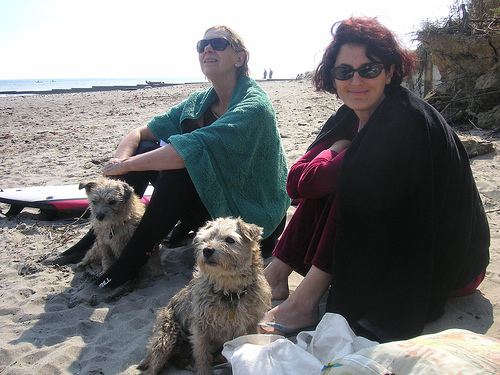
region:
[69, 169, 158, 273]
white and tan dog facing down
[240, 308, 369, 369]
white towel bunched up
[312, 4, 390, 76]
red burgundy short hair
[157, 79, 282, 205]
light green towel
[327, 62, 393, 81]
black cat eye shades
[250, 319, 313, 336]
white flip flops on a woman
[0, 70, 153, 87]
clear blue water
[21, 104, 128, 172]
brown disturbed sand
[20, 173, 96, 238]
red and white surfboard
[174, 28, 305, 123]
woman with blonde hair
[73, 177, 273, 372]
two tan colored dogs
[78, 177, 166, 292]
a dog looking down at the sand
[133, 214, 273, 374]
a dog looking upwards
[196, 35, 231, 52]
a pair of sunglasses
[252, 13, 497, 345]
woman with reddish colored hair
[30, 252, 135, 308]
feet buried in the sand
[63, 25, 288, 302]
a woman wearing a green shawl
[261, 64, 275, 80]
two people walking on the shore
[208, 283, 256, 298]
a dog's black collar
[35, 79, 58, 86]
people in the water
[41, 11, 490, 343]
two women sitting on the beach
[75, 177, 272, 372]
two dogs sitting on the beach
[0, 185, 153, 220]
a white and pink flotation device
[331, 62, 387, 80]
a pair of sunglasses on the woman's face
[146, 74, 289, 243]
a green towel on the woman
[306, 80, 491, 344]
a black towel on the woman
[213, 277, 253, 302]
a black dog collar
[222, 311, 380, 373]
a white bag on the ground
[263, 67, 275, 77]
two people standing in the distance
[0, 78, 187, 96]
ocean next to the beach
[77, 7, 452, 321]
Two dogs are on the beach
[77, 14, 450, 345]
Two women are sitting on the beach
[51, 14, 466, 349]
The photo was taken during the day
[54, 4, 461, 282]
Both women are wearing sunglasses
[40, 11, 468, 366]
Photo was taken during the day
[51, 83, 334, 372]
The dogs are the same breed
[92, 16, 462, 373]
Women are sitting on sand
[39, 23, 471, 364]
Women are sitting on the beach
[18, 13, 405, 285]
The ocean is in the background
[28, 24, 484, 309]
The women are looking in different directions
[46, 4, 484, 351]
Two women sitting on beach.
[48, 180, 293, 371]
Two small dogs sitting on beach.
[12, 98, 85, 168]
Footprints in the sand.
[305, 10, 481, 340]
A woman with dark hair.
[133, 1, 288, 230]
A woman with light colored hair.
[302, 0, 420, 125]
Black sunglasses on woman's face on the right.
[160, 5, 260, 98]
Black sunglasses on woman's face on the left.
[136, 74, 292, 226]
Green towel draped around woman's shoulders.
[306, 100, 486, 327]
A dark towel draped around woman's shoulders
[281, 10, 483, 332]
Long sleeve shirt worn by woman on right.